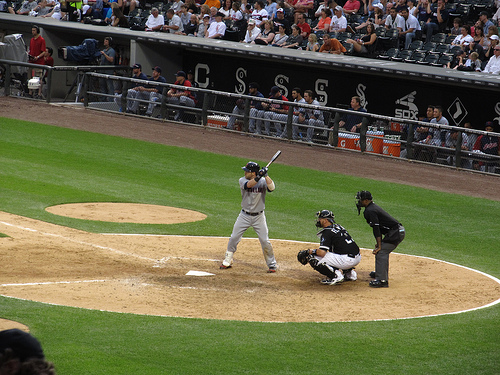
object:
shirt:
[362, 204, 403, 238]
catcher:
[295, 207, 362, 287]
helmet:
[314, 208, 335, 223]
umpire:
[355, 189, 407, 288]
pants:
[372, 227, 407, 280]